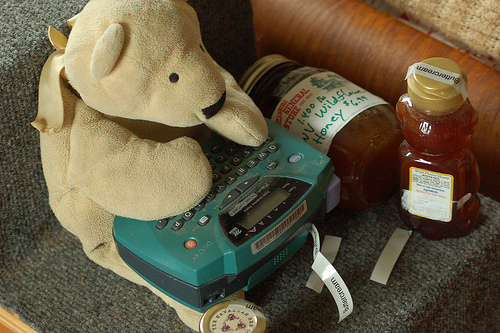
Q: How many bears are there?
A: One.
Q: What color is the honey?
A: Brown.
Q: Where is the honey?
A: To the right of the bear.